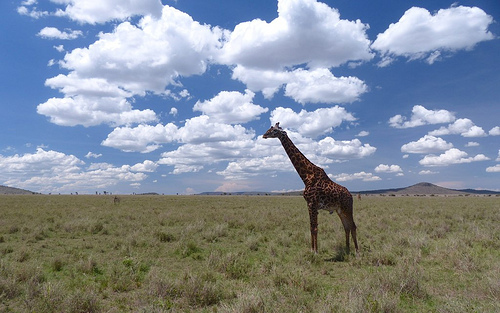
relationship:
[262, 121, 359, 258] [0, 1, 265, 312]
tall giraffe in plains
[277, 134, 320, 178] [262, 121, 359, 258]
neck of a giraffe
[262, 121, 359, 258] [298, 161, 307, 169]
giraffe has spots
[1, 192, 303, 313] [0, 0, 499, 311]
tall grass for grazing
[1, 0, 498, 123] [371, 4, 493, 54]
blue skies with white clouds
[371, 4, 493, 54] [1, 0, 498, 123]
white clouds in sky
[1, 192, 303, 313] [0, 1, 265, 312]
brown grass in plains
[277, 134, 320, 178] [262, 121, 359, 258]
long neck on giraffe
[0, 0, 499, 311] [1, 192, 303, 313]
blue sky over grass plains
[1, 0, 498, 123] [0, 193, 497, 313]
blue skies over grassy plains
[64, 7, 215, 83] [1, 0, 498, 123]
clouds in blue sky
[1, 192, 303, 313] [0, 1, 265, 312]
green grass on plains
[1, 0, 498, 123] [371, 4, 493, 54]
sky has white clouds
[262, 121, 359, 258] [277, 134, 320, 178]
tall giraffe with its long neck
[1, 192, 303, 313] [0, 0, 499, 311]
grass in african plains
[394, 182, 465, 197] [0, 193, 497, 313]
hill in grassy plains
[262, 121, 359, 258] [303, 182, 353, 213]
giraffe has a large abdomen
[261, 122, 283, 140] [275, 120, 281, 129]
giraffes head has horns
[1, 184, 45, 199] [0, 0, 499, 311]
hill in african plains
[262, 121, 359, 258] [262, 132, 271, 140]
giraffe has a large mouth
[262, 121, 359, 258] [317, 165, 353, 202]
giraffe has spots on h back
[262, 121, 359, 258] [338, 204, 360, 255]
giraffe has long legs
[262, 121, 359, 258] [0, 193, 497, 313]
giraffe on grassy plains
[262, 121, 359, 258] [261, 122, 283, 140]
giraffe has horns on h head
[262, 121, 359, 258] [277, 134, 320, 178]
giraffe has a long neck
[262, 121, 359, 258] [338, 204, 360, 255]
giraffe has powerful legs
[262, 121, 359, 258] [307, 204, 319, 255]
giraffe has long legs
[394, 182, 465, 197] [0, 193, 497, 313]
hill on grassy plains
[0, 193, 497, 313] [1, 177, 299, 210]
grassy plains are on horizon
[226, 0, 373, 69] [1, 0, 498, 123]
puffy clouds in sky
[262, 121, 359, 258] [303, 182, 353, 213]
giraffe has spots on h body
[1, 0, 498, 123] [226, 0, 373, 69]
sky has puffy clouds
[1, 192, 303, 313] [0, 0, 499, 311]
tall grass of african plains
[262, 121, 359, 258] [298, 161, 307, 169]
giraffe has brown spots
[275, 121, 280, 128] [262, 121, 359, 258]
two horns on giraffe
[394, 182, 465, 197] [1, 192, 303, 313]
hill on grass plains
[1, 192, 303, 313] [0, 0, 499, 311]
green grass on african plains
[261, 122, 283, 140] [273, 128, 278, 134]
giraffes head has two ears